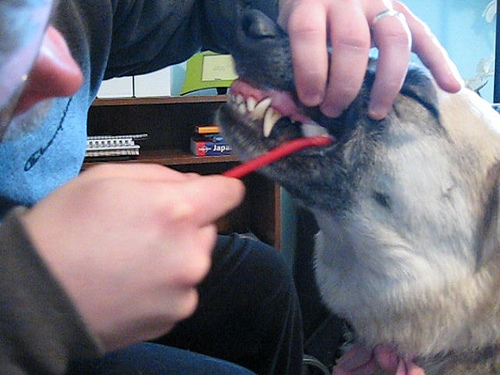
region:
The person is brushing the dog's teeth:
[220, 7, 498, 368]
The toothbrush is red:
[180, 115, 326, 185]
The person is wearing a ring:
[358, 1, 410, 28]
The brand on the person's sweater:
[20, 86, 122, 169]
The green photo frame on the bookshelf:
[179, 44, 251, 96]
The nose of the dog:
[216, 2, 286, 57]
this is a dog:
[199, 3, 493, 369]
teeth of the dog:
[220, 78, 293, 156]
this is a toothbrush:
[168, 93, 345, 220]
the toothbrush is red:
[209, 99, 342, 194]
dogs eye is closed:
[350, 49, 453, 153]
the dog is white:
[346, 158, 473, 345]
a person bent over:
[3, 0, 355, 374]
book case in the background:
[68, 40, 296, 267]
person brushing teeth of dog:
[1, 0, 470, 373]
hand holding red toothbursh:
[11, 94, 343, 361]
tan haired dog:
[413, 208, 490, 323]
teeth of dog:
[218, 80, 293, 153]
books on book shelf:
[182, 118, 237, 160]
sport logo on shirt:
[18, 91, 75, 189]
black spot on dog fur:
[358, 180, 403, 215]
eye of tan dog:
[397, 74, 447, 139]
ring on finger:
[366, 1, 406, 34]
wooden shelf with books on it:
[75, 86, 290, 261]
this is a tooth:
[261, 112, 281, 138]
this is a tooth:
[249, 96, 276, 121]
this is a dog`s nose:
[236, 4, 283, 50]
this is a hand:
[4, 159, 285, 330]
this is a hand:
[279, 1, 475, 115]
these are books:
[189, 119, 249, 161]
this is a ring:
[372, 6, 409, 21]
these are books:
[86, 131, 147, 159]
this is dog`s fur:
[337, 151, 499, 366]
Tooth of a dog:
[259, 107, 285, 144]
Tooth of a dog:
[253, 94, 272, 114]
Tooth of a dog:
[242, 89, 259, 113]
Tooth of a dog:
[234, 101, 247, 116]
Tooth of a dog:
[234, 89, 247, 104]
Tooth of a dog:
[230, 100, 237, 114]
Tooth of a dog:
[227, 89, 236, 101]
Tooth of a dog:
[225, 98, 236, 112]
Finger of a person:
[288, 5, 330, 117]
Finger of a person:
[327, 7, 369, 133]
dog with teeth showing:
[195, 0, 495, 345]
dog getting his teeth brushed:
[214, 8, 479, 350]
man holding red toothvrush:
[8, 5, 365, 347]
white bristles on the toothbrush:
[303, 122, 328, 134]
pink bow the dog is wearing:
[333, 332, 423, 374]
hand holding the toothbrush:
[51, 142, 233, 338]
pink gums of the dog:
[222, 75, 309, 125]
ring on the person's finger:
[372, 6, 405, 26]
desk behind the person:
[88, 74, 280, 246]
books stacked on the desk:
[177, 119, 236, 158]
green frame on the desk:
[173, 50, 249, 96]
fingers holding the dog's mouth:
[283, 15, 456, 117]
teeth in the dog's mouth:
[223, 90, 285, 131]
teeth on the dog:
[220, 76, 297, 141]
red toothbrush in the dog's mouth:
[205, 106, 339, 185]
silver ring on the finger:
[367, 8, 407, 28]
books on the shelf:
[177, 111, 239, 165]